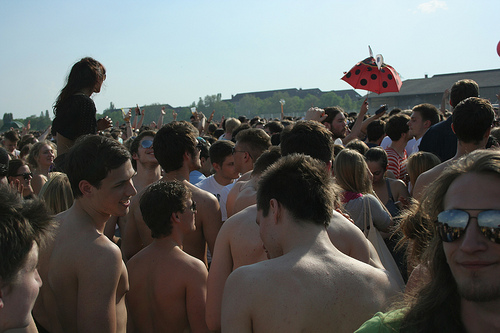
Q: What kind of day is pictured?
A: Warm.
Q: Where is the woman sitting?
A: On man's shoulders.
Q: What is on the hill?
A: Buildings.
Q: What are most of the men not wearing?
A: Shirts.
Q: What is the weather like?
A: Sky is clear and blue.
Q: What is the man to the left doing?
A: Looking up to the sky.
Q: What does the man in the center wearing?
A: He is wearing no shirt.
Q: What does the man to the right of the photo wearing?
A: Aviator style shades.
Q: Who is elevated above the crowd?
A: A girl sitting on someone's shoulders.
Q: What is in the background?
A: Pale blue sky above the people.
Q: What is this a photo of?
A: A crowd of people outside.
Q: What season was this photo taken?
A: Summer.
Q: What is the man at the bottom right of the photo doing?
A: Smiling.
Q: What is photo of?
A: Group of people.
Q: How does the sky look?
A: It is clear.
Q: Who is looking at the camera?
A: A man.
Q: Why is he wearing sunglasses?
A: To shade from the sun.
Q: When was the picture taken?
A: Daytime.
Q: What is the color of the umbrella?
A: Black and red.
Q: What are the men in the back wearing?
A: Nothing.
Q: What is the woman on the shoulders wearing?
A: Black top.